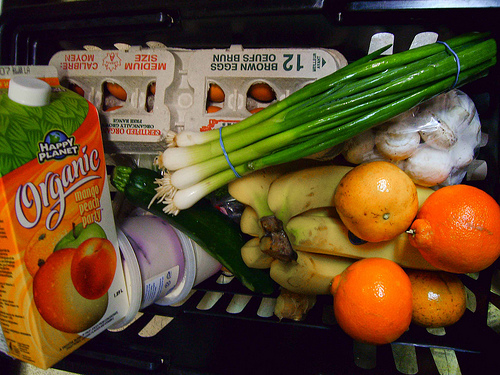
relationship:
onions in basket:
[155, 73, 445, 214] [3, 5, 492, 373]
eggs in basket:
[46, 40, 348, 158] [46, 49, 348, 158]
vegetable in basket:
[371, 119, 423, 162] [3, 5, 492, 373]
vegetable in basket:
[408, 100, 458, 152] [3, 5, 492, 373]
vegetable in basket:
[400, 142, 456, 190] [3, 5, 492, 373]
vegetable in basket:
[144, 29, 488, 221] [3, 5, 492, 373]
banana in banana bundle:
[228, 162, 292, 233] [225, 164, 435, 294]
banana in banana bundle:
[285, 207, 441, 270] [225, 164, 435, 294]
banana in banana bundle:
[282, 206, 423, 266] [225, 164, 435, 294]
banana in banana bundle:
[239, 237, 274, 270] [225, 164, 435, 294]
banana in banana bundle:
[225, 167, 275, 229] [225, 164, 435, 294]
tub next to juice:
[117, 214, 184, 330] [0, 91, 130, 353]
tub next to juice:
[157, 224, 220, 308] [0, 91, 130, 353]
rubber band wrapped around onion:
[211, 116, 243, 176] [142, 36, 488, 231]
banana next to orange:
[228, 162, 292, 233] [331, 150, 423, 240]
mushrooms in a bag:
[344, 85, 491, 196] [366, 88, 490, 175]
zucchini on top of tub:
[106, 162, 271, 290] [117, 214, 184, 330]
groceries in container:
[9, 37, 489, 355] [214, 284, 294, 372]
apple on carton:
[49, 218, 111, 248] [11, 61, 133, 373]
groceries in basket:
[9, 37, 489, 355] [3, 5, 492, 373]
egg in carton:
[249, 75, 274, 102] [42, 45, 344, 155]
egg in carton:
[199, 78, 227, 101] [42, 45, 344, 155]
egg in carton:
[104, 78, 124, 98] [42, 45, 344, 155]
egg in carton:
[146, 83, 157, 99] [42, 45, 344, 155]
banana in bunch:
[228, 162, 292, 233] [226, 161, 437, 296]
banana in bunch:
[286, 214, 433, 270] [226, 161, 437, 296]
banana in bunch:
[270, 251, 348, 291] [226, 161, 437, 296]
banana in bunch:
[227, 174, 277, 227] [226, 161, 437, 296]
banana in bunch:
[239, 234, 274, 267] [226, 161, 437, 296]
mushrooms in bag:
[359, 73, 460, 185] [378, 94, 480, 181]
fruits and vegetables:
[220, 166, 497, 347] [108, 31, 498, 297]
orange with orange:
[325, 252, 415, 348] [328, 150, 421, 247]